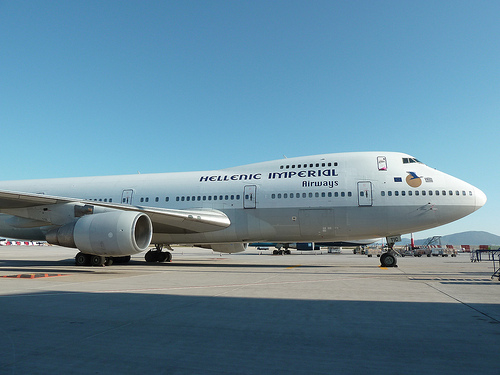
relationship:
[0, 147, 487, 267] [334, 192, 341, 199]
plane has window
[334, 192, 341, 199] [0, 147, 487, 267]
window on plane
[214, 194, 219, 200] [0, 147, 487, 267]
window on plane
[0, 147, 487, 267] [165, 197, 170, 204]
plane has window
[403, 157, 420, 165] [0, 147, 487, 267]
window on plane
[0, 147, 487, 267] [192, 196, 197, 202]
plane has window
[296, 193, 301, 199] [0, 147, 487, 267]
window of plane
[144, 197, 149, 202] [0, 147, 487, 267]
window of plane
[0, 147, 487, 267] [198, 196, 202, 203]
plane has window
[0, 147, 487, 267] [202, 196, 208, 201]
plane has window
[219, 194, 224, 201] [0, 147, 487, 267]
window of plane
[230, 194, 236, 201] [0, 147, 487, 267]
window on plane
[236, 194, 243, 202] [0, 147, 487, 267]
window on plane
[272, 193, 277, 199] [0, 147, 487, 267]
window of plane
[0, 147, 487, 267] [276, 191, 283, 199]
plane has window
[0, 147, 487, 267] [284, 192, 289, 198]
plane has window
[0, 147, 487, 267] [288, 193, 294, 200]
plane has window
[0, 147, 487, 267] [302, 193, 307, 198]
plane has window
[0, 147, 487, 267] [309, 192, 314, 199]
plane has window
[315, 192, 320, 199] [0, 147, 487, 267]
window on plane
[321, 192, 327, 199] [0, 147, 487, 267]
window on plane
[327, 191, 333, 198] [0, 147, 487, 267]
window on plane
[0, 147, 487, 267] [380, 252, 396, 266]
plane has wheel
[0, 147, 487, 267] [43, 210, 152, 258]
plane has engine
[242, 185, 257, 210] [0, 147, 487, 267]
door on plane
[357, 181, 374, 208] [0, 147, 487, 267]
door on plane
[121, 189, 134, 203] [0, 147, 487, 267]
door on plane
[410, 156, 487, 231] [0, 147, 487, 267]
tip of plane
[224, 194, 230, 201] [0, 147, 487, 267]
window on plane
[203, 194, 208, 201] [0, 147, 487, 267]
window on plane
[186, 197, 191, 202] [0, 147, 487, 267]
window on plane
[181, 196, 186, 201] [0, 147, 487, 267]
window on plane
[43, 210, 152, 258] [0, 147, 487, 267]
engine on plane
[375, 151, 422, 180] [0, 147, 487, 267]
cock-pit on jetliner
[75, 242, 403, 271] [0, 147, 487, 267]
landing-gear on jet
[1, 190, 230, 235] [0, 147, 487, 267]
right wing on jet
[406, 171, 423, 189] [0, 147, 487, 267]
emblem on side of jet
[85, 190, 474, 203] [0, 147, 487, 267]
windows on side of jet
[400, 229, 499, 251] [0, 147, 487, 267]
hillside behind plane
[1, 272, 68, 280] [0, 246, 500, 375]
orange paint on ground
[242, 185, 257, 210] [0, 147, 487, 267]
door on side of jet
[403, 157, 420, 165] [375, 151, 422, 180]
window for cockpit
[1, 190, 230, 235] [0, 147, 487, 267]
wing on plane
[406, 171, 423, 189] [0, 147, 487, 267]
sign on plane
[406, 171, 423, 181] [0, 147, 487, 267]
blue-bird on plane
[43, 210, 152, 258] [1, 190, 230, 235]
blades under wing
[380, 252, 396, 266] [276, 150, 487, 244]
wheels on front